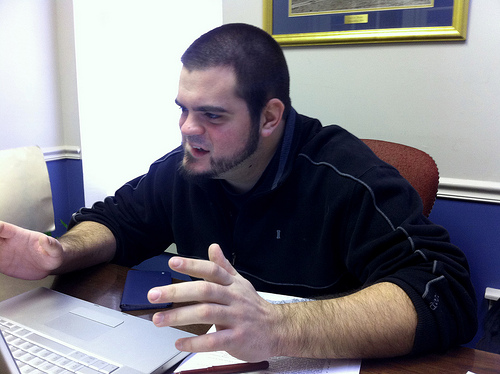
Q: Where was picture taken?
A: Conference room.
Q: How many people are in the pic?
A: One.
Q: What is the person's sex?
A: Male.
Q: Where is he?
A: In a chair.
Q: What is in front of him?
A: A table.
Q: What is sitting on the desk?
A: A laptop computer.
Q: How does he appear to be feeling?
A: Frustrated.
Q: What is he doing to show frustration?
A: His facial expression.